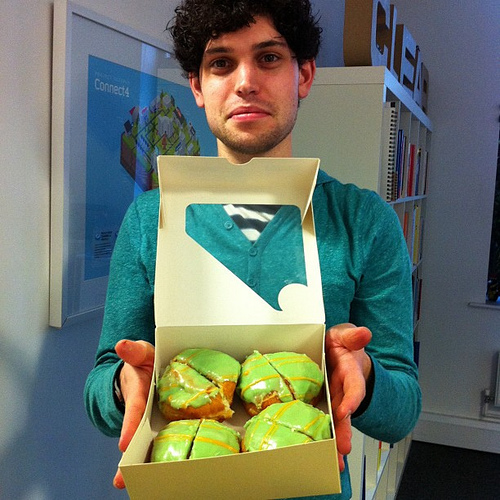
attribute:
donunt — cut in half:
[153, 415, 237, 463]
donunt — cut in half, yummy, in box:
[159, 345, 234, 416]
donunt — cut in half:
[240, 351, 320, 404]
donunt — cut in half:
[239, 397, 328, 455]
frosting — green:
[163, 352, 238, 402]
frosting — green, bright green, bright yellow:
[246, 349, 318, 394]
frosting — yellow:
[154, 420, 234, 459]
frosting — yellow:
[246, 405, 326, 447]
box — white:
[116, 152, 343, 495]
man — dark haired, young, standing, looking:
[85, 3, 421, 500]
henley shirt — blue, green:
[81, 173, 420, 500]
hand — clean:
[102, 332, 157, 489]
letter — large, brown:
[344, 1, 394, 70]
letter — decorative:
[388, 6, 401, 79]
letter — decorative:
[393, 22, 417, 87]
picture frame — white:
[50, 4, 230, 331]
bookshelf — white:
[265, 65, 423, 498]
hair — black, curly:
[171, 2, 322, 67]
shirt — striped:
[224, 201, 281, 245]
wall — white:
[3, 2, 219, 500]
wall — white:
[308, 1, 499, 451]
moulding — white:
[411, 411, 493, 452]